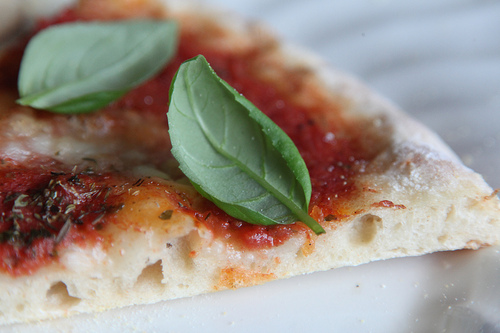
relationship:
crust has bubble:
[1, 1, 499, 316] [137, 259, 165, 292]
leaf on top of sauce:
[166, 53, 324, 237] [0, 0, 368, 278]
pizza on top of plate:
[0, 4, 499, 316] [1, 2, 494, 332]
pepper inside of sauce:
[307, 118, 315, 127] [0, 0, 368, 278]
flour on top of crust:
[384, 131, 445, 196] [1, 1, 499, 316]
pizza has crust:
[0, 4, 499, 316] [1, 1, 499, 316]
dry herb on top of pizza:
[0, 166, 126, 263] [0, 4, 499, 316]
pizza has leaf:
[0, 4, 499, 316] [166, 53, 324, 237]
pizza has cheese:
[0, 4, 499, 316] [2, 103, 189, 195]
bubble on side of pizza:
[137, 259, 165, 292] [0, 4, 499, 316]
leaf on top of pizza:
[166, 53, 324, 237] [0, 4, 499, 316]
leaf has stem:
[166, 53, 324, 237] [186, 70, 322, 234]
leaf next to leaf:
[166, 53, 324, 237] [17, 19, 181, 112]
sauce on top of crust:
[0, 0, 368, 278] [1, 1, 499, 316]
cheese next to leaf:
[2, 103, 189, 195] [166, 53, 324, 237]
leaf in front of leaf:
[166, 53, 324, 237] [17, 19, 181, 112]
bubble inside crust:
[137, 259, 165, 292] [1, 1, 499, 316]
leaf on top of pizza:
[17, 19, 181, 112] [0, 4, 499, 316]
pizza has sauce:
[0, 4, 499, 316] [0, 0, 368, 278]